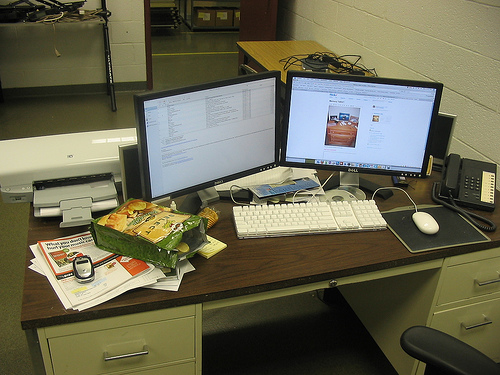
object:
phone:
[64, 250, 103, 288]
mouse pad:
[381, 197, 493, 252]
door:
[239, 12, 275, 50]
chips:
[90, 194, 212, 271]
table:
[234, 38, 380, 90]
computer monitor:
[270, 67, 444, 180]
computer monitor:
[134, 66, 280, 202]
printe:
[0, 122, 155, 231]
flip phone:
[66, 249, 99, 287]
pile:
[14, 222, 115, 300]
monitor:
[131, 68, 444, 201]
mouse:
[411, 209, 441, 238]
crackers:
[93, 185, 212, 279]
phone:
[428, 151, 497, 234]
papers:
[25, 223, 194, 309]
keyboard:
[230, 197, 385, 239]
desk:
[17, 130, 496, 372]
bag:
[81, 177, 221, 300]